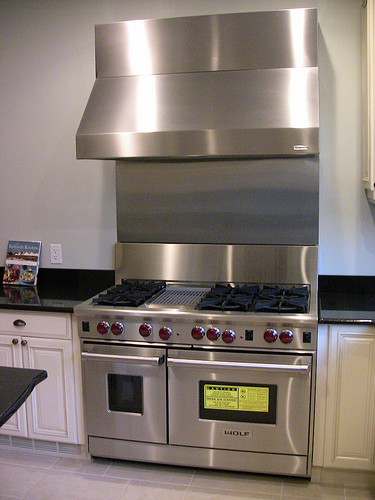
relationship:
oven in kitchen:
[82, 340, 315, 484] [2, 2, 370, 499]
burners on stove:
[97, 281, 312, 313] [73, 274, 329, 308]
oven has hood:
[82, 340, 315, 484] [71, 5, 337, 167]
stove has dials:
[73, 274, 329, 308] [83, 312, 307, 348]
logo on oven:
[214, 426, 260, 440] [82, 340, 315, 484]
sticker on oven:
[198, 380, 277, 416] [82, 340, 315, 484]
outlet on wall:
[47, 241, 66, 267] [2, 4, 373, 271]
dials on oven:
[83, 312, 307, 348] [82, 340, 315, 484]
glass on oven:
[102, 371, 297, 427] [82, 340, 315, 484]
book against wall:
[2, 235, 44, 295] [2, 4, 373, 271]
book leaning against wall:
[2, 235, 44, 295] [2, 4, 373, 271]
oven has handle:
[82, 340, 315, 484] [78, 345, 313, 379]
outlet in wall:
[47, 241, 66, 267] [2, 4, 373, 271]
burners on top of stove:
[97, 281, 312, 313] [73, 274, 329, 308]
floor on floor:
[0, 433, 375, 500] [0, 433, 375, 500]